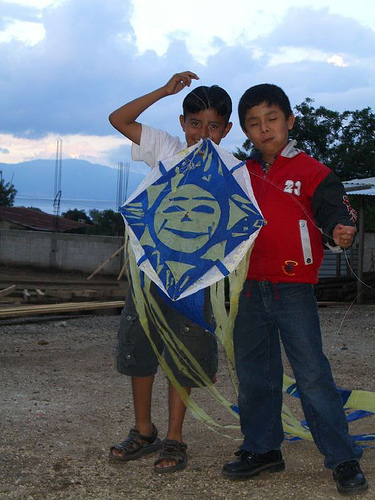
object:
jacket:
[238, 140, 356, 286]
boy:
[107, 70, 241, 475]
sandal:
[107, 426, 164, 459]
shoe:
[219, 445, 286, 480]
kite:
[117, 135, 374, 457]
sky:
[0, 0, 374, 215]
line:
[6, 193, 138, 214]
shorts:
[113, 283, 217, 390]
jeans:
[231, 277, 359, 467]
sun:
[136, 161, 252, 286]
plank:
[0, 298, 127, 320]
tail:
[119, 233, 374, 447]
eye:
[268, 113, 280, 126]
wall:
[0, 229, 126, 279]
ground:
[0, 275, 374, 498]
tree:
[231, 96, 375, 180]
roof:
[341, 175, 375, 199]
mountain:
[0, 149, 150, 212]